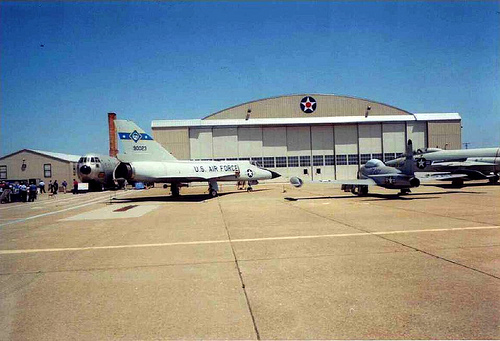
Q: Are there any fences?
A: No, there are no fences.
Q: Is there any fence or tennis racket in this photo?
A: No, there are no fences or rackets.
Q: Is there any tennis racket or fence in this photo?
A: No, there are no fences or rackets.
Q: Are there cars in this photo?
A: No, there are no cars.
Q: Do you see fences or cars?
A: No, there are no cars or fences.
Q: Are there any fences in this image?
A: No, there are no fences.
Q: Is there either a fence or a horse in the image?
A: No, there are no fences or horses.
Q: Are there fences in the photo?
A: No, there are no fences.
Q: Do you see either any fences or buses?
A: No, there are no fences or buses.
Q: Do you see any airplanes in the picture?
A: Yes, there is an airplane.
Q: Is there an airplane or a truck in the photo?
A: Yes, there is an airplane.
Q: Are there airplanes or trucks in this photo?
A: Yes, there is an airplane.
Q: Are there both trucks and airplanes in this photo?
A: No, there is an airplane but no trucks.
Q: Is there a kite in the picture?
A: No, there are no kites.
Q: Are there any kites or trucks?
A: No, there are no kites or trucks.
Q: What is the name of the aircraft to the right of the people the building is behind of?
A: The aircraft is an airplane.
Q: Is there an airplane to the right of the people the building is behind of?
A: Yes, there is an airplane to the right of the people.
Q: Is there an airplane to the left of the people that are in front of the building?
A: No, the airplane is to the right of the people.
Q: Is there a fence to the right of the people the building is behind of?
A: No, there is an airplane to the right of the people.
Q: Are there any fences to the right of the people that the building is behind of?
A: No, there is an airplane to the right of the people.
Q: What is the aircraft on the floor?
A: The aircraft is an airplane.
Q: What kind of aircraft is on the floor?
A: The aircraft is an airplane.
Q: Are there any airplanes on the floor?
A: Yes, there is an airplane on the floor.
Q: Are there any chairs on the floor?
A: No, there is an airplane on the floor.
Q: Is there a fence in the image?
A: No, there are no fences.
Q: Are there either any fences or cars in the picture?
A: No, there are no fences or cars.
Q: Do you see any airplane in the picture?
A: Yes, there is an airplane.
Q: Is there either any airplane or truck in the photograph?
A: Yes, there is an airplane.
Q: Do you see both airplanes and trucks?
A: No, there is an airplane but no trucks.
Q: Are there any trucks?
A: No, there are no trucks.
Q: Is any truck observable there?
A: No, there are no trucks.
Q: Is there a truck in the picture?
A: No, there are no trucks.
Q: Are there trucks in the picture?
A: No, there are no trucks.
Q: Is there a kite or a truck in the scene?
A: No, there are no trucks or kites.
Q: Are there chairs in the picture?
A: No, there are no chairs.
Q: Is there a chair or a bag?
A: No, there are no chairs or bags.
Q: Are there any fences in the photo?
A: No, there are no fences.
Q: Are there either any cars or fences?
A: No, there are no fences or cars.